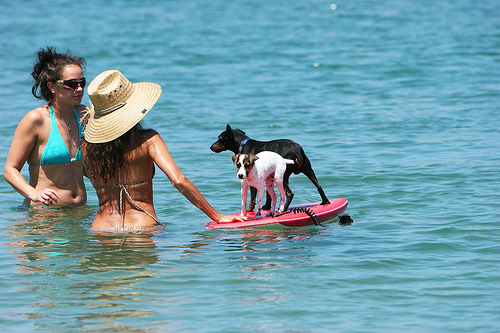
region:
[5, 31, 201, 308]
The people are in the water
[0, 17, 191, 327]
Two ladies are doing some swimming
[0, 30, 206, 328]
Two people are at the beach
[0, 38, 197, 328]
One person is wearing a straw hat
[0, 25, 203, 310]
A person is wearing dark sunglasses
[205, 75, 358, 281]
Two dogs are on a surfboard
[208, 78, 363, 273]
Two dogs are trying not to get wet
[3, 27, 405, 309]
Two dogs are swimming with their masters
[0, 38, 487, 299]
Two people are with their dogs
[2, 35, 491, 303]
Two dogs and two people are swimming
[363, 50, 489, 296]
calm ocean water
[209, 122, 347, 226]
two dogs standing on wave board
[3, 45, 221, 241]
two women in the water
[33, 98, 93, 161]
turquoise bikini top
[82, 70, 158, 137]
straw hat to shade face from sun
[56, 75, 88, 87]
sunglasses to shade eyes from sun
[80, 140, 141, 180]
hair is down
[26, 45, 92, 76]
hair is up in bun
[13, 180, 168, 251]
water only goes up to their waist, so it must be shallow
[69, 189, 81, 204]
belly button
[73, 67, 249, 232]
A woman wearing a hat.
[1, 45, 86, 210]
A woman wearing sunglasses.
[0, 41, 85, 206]
A woman wearing a blue swim suit.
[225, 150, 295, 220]
A white dog with brown ears.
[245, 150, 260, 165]
The ear of a dog.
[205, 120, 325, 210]
A dog wearing a blue collar.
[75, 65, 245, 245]
A woman standing in the water.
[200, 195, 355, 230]
A red raft in the water.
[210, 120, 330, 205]
A black dog in the water.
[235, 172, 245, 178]
The nose of a dog.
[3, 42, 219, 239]
women in the water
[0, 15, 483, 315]
body of water with people and animals in it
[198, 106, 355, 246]
dogs on red board in water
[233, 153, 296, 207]
white dog on board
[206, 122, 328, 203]
black dog on board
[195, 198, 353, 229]
red board dogs are on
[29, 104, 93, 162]
blue swim top of woman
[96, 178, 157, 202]
tie of swim top to woman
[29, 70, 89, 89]
sunglasses on the woman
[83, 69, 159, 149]
hat on woman in water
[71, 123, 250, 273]
woman standing in the water with bikini on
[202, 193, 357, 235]
red boogie board in water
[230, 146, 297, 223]
white jack russell looking dog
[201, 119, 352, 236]
two dogs on boogie board in water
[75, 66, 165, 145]
tan colored straw hat on womans head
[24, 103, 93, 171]
blue bikini top on woman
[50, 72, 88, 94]
woman's sun glasses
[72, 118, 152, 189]
woman's long dark hair coming out from under hat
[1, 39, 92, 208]
dark haired woman in blue bikini top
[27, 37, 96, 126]
dark haired woman wearing sunglasses